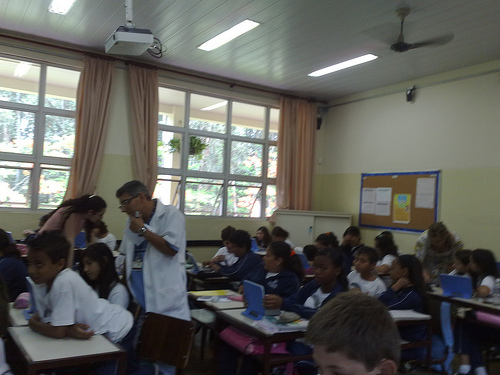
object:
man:
[115, 180, 191, 322]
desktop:
[222, 307, 308, 335]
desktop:
[10, 325, 124, 362]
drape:
[64, 57, 114, 201]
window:
[0, 57, 40, 109]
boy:
[28, 226, 159, 373]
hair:
[269, 240, 304, 280]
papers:
[414, 175, 438, 208]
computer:
[241, 281, 280, 322]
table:
[220, 306, 318, 373]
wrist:
[136, 223, 151, 239]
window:
[230, 139, 263, 178]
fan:
[360, 1, 454, 55]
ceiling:
[1, 0, 500, 103]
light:
[196, 19, 260, 52]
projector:
[103, 0, 168, 61]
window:
[265, 107, 279, 142]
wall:
[320, 61, 500, 261]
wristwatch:
[137, 225, 149, 238]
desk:
[10, 314, 128, 374]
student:
[236, 240, 304, 300]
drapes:
[276, 98, 317, 210]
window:
[187, 133, 225, 175]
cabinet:
[272, 215, 314, 247]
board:
[356, 169, 441, 232]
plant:
[169, 135, 208, 154]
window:
[190, 91, 228, 134]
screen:
[244, 279, 266, 315]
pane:
[227, 136, 263, 178]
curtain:
[125, 61, 158, 198]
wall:
[1, 39, 316, 266]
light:
[306, 52, 376, 77]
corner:
[306, 203, 325, 212]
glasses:
[116, 194, 137, 212]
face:
[117, 191, 143, 218]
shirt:
[32, 268, 134, 343]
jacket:
[118, 197, 190, 323]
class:
[0, 0, 500, 375]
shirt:
[38, 206, 80, 234]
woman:
[32, 195, 106, 267]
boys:
[346, 245, 388, 298]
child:
[305, 292, 402, 375]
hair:
[302, 290, 401, 371]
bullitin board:
[360, 169, 440, 231]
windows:
[153, 170, 184, 209]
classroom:
[0, 0, 500, 374]